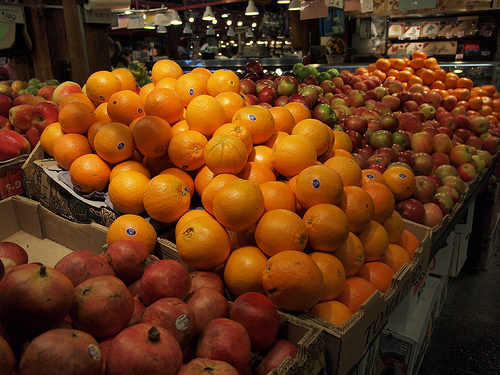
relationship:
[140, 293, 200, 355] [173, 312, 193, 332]
pomegranate with a sticker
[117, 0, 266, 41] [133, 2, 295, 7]
many lights hanging from ceiling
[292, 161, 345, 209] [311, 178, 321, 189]
orange with a blue sticker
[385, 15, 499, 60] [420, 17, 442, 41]
shelfs with boxed items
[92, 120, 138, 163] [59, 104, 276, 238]
navel orange piles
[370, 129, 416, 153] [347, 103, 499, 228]
green and red apples in a bin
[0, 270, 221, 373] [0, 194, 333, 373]
pomegranets stacks in a box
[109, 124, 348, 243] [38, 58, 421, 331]
oranges apples on display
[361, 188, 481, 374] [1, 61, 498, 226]
cardboard bins with fruit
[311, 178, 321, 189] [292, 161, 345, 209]
blue sticker with a orange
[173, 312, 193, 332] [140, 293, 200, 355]
white sticker with a pomegranete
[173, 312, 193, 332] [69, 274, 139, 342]
white sticker with a pomegranete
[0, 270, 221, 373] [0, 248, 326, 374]
pomegranets oranges on display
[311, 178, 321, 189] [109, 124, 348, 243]
blue stickers on oranges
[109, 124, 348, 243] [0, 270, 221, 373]
oranges next to pomegranates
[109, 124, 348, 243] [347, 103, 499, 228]
oranges and apples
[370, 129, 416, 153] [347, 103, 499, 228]
green and red apples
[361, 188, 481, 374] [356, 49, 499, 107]
boxes of tangerines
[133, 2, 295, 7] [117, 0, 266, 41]
ceiling hanging light fixtures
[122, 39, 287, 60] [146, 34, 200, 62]
background are workers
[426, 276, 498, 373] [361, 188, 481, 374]
floor has more boxes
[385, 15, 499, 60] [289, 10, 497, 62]
seafood boxes in background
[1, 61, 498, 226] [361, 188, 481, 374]
fruit in boxes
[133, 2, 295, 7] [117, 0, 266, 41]
ceiling hanging lights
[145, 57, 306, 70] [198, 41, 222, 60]
counter has a basket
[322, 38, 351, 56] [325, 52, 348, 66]
flowers in a basket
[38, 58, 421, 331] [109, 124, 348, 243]
pile of several oranges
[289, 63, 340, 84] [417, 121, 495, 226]
green and red apples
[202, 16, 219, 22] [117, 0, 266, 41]
white lights hanging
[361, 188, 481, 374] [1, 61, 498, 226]
boxes of cardboard under fruit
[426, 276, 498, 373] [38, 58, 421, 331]
floor beneath fruit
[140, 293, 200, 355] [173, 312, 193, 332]
pomegranate has a sticker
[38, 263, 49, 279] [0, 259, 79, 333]
stem of a pomegranate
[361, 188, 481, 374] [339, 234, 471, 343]
boxes under shelf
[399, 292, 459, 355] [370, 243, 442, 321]
boxes under table